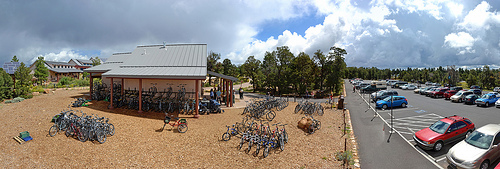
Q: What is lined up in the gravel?
A: Bikes.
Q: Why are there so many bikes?
A: They are to be rented or sold.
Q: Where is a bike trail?
A: Between the two parking lots.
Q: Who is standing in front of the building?
A: A group of people.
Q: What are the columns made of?
A: Wood.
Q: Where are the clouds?
A: In the sky.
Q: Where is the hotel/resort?
A: Behind the bike shack.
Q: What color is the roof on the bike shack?
A: Gray.